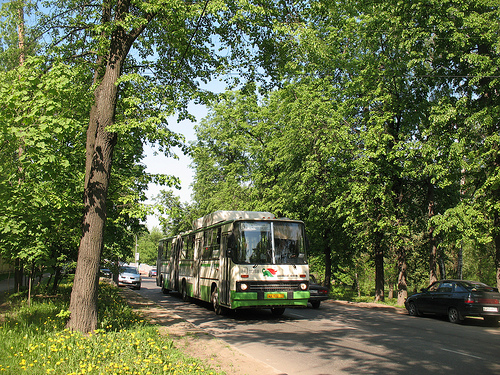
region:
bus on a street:
[151, 185, 342, 321]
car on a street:
[393, 277, 496, 329]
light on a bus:
[235, 277, 252, 294]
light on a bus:
[295, 280, 310, 292]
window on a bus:
[231, 216, 309, 261]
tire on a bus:
[200, 275, 220, 315]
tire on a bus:
[171, 267, 188, 299]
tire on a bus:
[153, 265, 165, 302]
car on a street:
[110, 260, 143, 286]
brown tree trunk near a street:
[67, 98, 119, 338]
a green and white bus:
[194, 199, 321, 338]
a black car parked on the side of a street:
[401, 258, 493, 347]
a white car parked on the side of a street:
[106, 254, 142, 294]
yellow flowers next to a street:
[74, 319, 176, 374]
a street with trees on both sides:
[46, 108, 432, 364]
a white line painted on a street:
[410, 337, 486, 367]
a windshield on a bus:
[232, 204, 312, 264]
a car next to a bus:
[273, 252, 339, 319]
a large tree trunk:
[58, 12, 139, 353]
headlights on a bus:
[228, 278, 315, 300]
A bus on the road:
[156, 209, 311, 311]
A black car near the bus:
[406, 278, 498, 323]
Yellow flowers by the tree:
[28, 320, 211, 374]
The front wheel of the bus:
[211, 288, 218, 308]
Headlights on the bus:
[238, 280, 308, 290]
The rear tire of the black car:
[446, 309, 461, 322]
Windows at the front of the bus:
[236, 220, 303, 260]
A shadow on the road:
[270, 305, 498, 374]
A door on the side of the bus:
[222, 231, 231, 304]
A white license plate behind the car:
[479, 305, 498, 315]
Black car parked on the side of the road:
[404, 279, 498, 325]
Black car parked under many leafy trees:
[403, 278, 499, 323]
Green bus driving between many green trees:
[155, 211, 312, 317]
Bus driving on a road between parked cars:
[156, 208, 312, 319]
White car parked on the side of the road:
[118, 264, 144, 286]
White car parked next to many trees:
[115, 263, 142, 289]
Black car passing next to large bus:
[307, 274, 332, 308]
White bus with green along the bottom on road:
[154, 211, 311, 316]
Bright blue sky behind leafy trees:
[1, 0, 498, 232]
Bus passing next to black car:
[156, 209, 310, 318]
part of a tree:
[402, 175, 419, 197]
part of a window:
[246, 224, 251, 249]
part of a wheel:
[211, 273, 222, 304]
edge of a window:
[271, 238, 283, 261]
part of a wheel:
[446, 300, 459, 325]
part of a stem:
[377, 255, 382, 293]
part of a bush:
[136, 342, 145, 352]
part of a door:
[426, 293, 439, 310]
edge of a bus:
[263, 274, 272, 286]